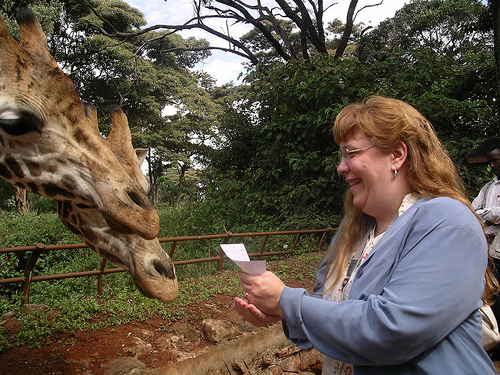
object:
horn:
[106, 104, 131, 140]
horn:
[83, 103, 100, 133]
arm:
[239, 197, 489, 365]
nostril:
[127, 191, 146, 209]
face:
[337, 126, 390, 213]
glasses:
[338, 145, 376, 162]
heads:
[0, 2, 160, 240]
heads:
[58, 103, 178, 304]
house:
[35, 287, 130, 339]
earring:
[395, 168, 399, 177]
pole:
[0, 227, 340, 254]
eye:
[0, 110, 40, 136]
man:
[470, 140, 500, 307]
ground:
[370, 128, 462, 192]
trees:
[350, 0, 497, 63]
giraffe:
[0, 3, 160, 240]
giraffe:
[55, 104, 179, 304]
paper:
[219, 243, 266, 276]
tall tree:
[84, 0, 383, 108]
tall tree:
[0, 0, 214, 136]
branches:
[85, 0, 260, 66]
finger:
[247, 304, 268, 323]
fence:
[0, 228, 339, 309]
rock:
[199, 318, 243, 344]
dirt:
[70, 317, 207, 350]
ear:
[391, 141, 408, 171]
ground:
[9, 228, 412, 373]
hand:
[240, 271, 286, 316]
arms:
[471, 181, 494, 224]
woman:
[232, 94, 498, 375]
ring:
[243, 293, 249, 299]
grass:
[0, 253, 324, 352]